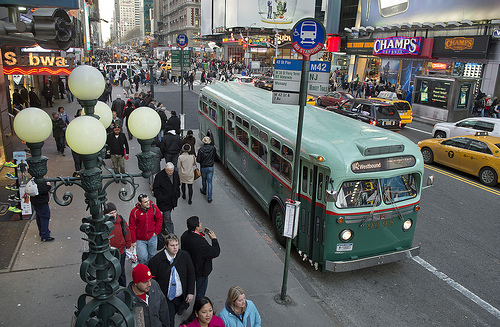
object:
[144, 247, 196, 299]
jacket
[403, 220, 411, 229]
light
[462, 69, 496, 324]
road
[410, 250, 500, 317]
line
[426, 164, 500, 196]
line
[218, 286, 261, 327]
people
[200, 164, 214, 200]
jeans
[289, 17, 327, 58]
sign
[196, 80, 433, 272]
bus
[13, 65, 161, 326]
lamp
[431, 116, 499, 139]
car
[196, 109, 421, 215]
red strip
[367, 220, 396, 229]
text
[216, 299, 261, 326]
blue jacket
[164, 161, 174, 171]
white head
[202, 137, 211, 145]
white head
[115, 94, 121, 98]
white head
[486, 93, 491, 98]
white head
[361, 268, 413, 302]
ground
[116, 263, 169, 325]
man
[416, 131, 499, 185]
cab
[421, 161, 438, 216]
street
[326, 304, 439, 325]
tarmacked road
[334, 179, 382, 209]
window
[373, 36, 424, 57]
sign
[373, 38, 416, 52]
letters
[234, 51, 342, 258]
street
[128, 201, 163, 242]
jacket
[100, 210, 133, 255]
jacket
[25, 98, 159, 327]
light pole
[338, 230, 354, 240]
head light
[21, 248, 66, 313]
sidewalk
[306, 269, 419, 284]
street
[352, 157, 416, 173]
sign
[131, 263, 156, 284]
hat